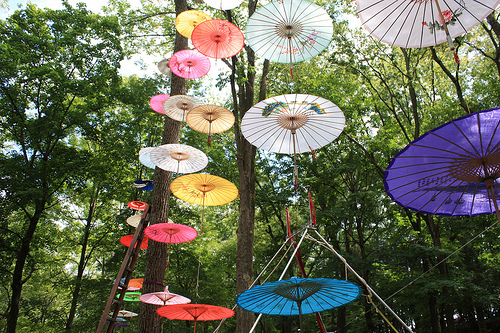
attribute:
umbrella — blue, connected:
[234, 273, 370, 321]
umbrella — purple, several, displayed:
[387, 107, 499, 223]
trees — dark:
[3, 8, 124, 328]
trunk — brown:
[234, 150, 260, 331]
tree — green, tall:
[140, 17, 187, 330]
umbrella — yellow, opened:
[167, 170, 243, 210]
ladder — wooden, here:
[94, 201, 150, 330]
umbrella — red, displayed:
[150, 301, 234, 324]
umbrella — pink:
[141, 221, 200, 247]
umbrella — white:
[243, 4, 336, 65]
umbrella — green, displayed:
[117, 291, 139, 303]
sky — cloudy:
[41, 3, 169, 73]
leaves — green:
[19, 6, 92, 61]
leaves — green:
[337, 81, 413, 120]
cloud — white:
[35, 1, 64, 13]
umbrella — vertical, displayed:
[184, 105, 237, 146]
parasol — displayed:
[229, 89, 357, 159]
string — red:
[305, 193, 320, 225]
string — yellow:
[366, 295, 396, 331]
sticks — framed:
[282, 221, 319, 242]